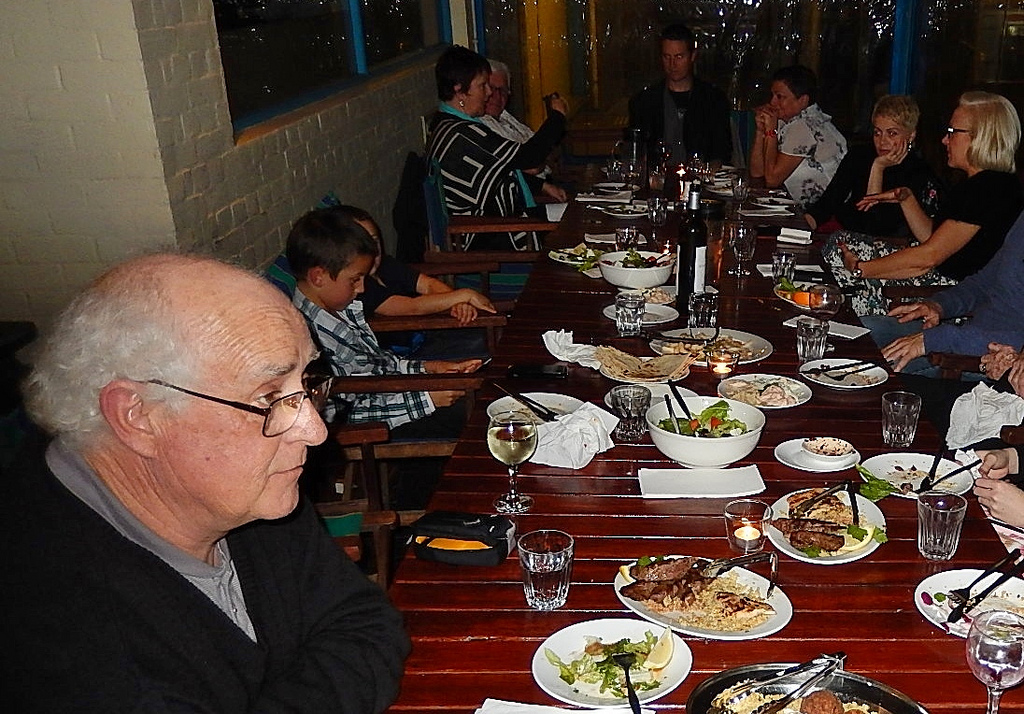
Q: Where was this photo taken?
A: In a restaurant.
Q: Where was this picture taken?
A: In a restaurant.